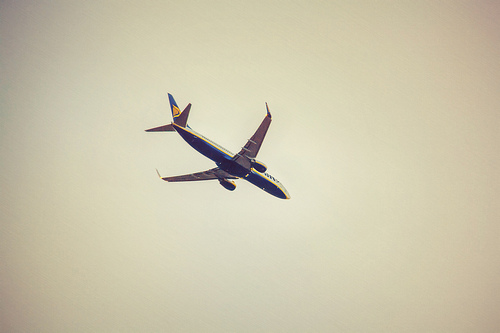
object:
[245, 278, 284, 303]
part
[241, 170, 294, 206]
plane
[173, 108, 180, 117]
yellow logo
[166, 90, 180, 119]
blue tail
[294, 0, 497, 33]
sky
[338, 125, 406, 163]
cloudy sky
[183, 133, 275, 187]
fuselage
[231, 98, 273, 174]
right wing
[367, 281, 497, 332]
cloudy sky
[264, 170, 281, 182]
windows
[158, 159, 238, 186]
wing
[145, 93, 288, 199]
airplane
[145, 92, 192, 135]
tail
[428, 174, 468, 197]
sky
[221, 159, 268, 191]
engines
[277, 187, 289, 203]
nose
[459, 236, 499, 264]
sky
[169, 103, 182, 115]
lettering